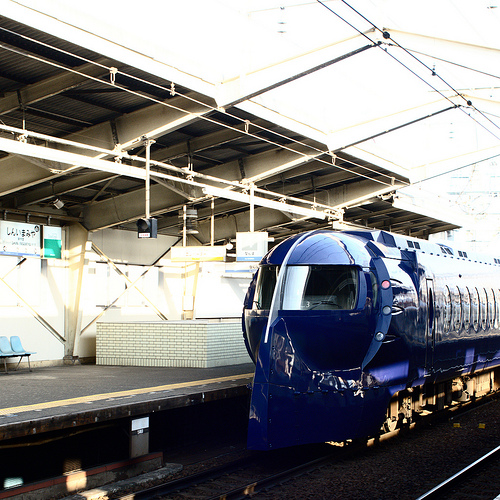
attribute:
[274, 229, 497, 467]
train — blue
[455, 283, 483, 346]
window — glass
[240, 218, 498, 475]
train — blue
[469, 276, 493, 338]
window — glass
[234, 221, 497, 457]
train — blue, shiny, bright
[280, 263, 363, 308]
window — large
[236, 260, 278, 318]
window — large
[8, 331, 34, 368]
chair — green, plastic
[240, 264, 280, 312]
window — glass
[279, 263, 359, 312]
window — glass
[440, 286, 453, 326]
window — glass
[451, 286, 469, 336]
window — glass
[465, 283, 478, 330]
window — glass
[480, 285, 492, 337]
window — glass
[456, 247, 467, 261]
window — glass